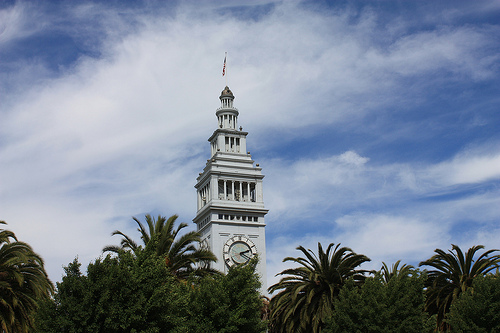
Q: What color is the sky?
A: Blue.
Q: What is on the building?
A: A clock.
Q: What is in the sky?
A: Clouds.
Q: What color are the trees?
A: Green.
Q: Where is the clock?
A: Above the trees.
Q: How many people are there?
A: None.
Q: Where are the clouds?
A: In the sky.